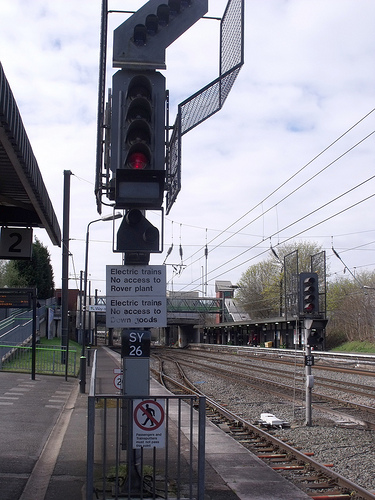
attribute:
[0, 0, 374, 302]
sky — cloudy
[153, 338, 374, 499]
train track — rusted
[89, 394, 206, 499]
gate — metal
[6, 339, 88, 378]
ground — grassy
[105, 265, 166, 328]
sign — white, square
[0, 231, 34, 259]
sign — white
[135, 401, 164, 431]
no walking symbol — red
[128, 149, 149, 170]
stoplight — red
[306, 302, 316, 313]
stoplight — red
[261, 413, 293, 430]
control box — white